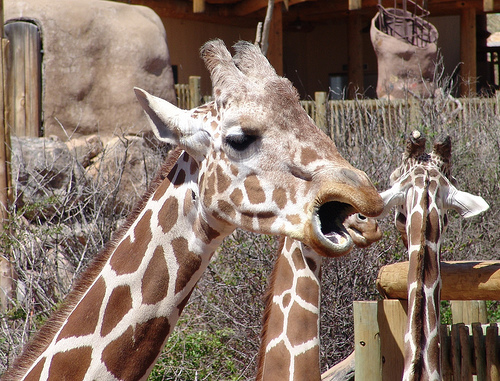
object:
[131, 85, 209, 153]
ear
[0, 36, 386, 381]
giraffe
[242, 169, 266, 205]
spots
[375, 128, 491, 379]
giraffe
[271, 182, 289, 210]
spots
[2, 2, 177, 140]
rock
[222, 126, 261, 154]
eye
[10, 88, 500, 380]
enclosure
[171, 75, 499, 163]
fence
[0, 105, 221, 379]
neck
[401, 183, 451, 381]
neck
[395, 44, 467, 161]
branches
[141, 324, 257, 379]
grass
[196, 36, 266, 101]
ossicones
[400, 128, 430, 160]
ossicones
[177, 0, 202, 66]
wall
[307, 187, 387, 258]
open mouth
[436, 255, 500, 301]
shadow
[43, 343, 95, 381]
brown spots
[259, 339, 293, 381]
brown spots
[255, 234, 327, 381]
giraffe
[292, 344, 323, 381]
brown spots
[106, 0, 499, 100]
house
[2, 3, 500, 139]
background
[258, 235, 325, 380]
neck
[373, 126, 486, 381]
back view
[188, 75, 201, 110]
wood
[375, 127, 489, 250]
back of head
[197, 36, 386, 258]
face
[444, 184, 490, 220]
ear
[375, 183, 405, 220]
ear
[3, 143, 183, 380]
mane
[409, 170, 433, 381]
mane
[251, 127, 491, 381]
two giraffes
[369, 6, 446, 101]
boulder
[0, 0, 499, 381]
photo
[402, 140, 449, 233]
back